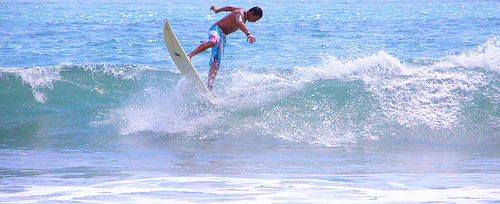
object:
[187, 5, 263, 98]
man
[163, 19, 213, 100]
surfboard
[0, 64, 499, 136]
waves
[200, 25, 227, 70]
shorts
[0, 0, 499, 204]
ocean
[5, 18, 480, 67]
ripples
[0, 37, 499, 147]
foam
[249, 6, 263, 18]
hair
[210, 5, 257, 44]
arms